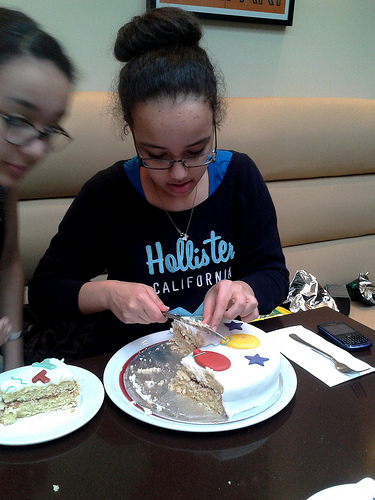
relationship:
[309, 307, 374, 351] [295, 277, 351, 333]
cell phone on table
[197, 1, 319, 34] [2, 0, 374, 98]
frame on wall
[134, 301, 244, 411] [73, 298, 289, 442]
cake on plate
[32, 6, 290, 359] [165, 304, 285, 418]
girl cutting cake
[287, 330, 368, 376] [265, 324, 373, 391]
fork on top of napkin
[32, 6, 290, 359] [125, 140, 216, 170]
girl wearing glasses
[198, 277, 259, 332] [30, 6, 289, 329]
hand of woman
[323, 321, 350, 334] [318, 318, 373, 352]
screen on cellphone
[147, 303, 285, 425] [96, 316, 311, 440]
cake on plate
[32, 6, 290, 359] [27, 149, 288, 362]
girl wearing black shirt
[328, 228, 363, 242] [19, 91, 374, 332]
back of table bench